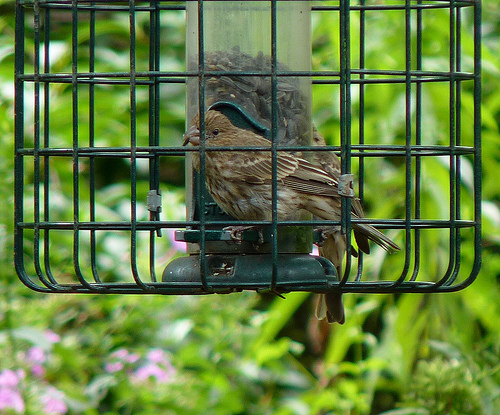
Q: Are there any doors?
A: Yes, there is a door.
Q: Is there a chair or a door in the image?
A: Yes, there is a door.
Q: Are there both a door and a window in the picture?
A: No, there is a door but no windows.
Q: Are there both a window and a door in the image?
A: No, there is a door but no windows.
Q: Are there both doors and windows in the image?
A: No, there is a door but no windows.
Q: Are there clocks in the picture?
A: No, there are no clocks.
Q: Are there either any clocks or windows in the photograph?
A: No, there are no clocks or windows.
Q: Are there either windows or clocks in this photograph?
A: No, there are no clocks or windows.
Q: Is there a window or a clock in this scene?
A: No, there are no clocks or windows.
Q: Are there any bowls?
A: No, there are no bowls.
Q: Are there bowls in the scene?
A: No, there are no bowls.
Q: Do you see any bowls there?
A: No, there are no bowls.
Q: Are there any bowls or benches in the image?
A: No, there are no bowls or benches.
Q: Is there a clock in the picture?
A: No, there are no clocks.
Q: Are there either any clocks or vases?
A: No, there are no clocks or vases.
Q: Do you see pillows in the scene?
A: No, there are no pillows.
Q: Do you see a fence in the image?
A: No, there are no fences.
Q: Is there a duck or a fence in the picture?
A: No, there are no fences or ducks.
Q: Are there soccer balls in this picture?
A: No, there are no soccer balls.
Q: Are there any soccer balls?
A: No, there are no soccer balls.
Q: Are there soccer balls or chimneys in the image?
A: No, there are no soccer balls or chimneys.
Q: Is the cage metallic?
A: Yes, the cage is metallic.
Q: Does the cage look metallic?
A: Yes, the cage is metallic.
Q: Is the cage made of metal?
A: Yes, the cage is made of metal.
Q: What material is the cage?
A: The cage is made of metal.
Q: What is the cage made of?
A: The cage is made of metal.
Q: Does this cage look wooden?
A: No, the cage is metallic.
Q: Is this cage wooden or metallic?
A: The cage is metallic.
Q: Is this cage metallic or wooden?
A: The cage is metallic.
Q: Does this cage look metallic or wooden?
A: The cage is metallic.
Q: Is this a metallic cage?
A: Yes, this is a metallic cage.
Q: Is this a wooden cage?
A: No, this is a metallic cage.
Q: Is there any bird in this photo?
A: Yes, there is a bird.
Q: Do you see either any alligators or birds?
A: Yes, there is a bird.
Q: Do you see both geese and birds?
A: No, there is a bird but no geese.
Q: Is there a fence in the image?
A: No, there are no fences.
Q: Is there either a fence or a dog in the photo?
A: No, there are no fences or dogs.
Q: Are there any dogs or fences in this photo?
A: No, there are no fences or dogs.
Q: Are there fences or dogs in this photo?
A: No, there are no fences or dogs.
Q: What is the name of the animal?
A: The animal is a bird.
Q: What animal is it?
A: The animal is a bird.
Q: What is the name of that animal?
A: This is a bird.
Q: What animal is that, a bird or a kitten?
A: This is a bird.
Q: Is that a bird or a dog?
A: That is a bird.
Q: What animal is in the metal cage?
A: The bird is in the cage.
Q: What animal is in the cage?
A: The animal is a bird.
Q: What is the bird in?
A: The bird is in the cage.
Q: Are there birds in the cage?
A: Yes, there is a bird in the cage.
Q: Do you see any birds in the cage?
A: Yes, there is a bird in the cage.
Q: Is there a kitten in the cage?
A: No, there is a bird in the cage.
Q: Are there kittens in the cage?
A: No, there is a bird in the cage.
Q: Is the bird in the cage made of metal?
A: Yes, the bird is in the cage.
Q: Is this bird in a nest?
A: No, the bird is in the cage.